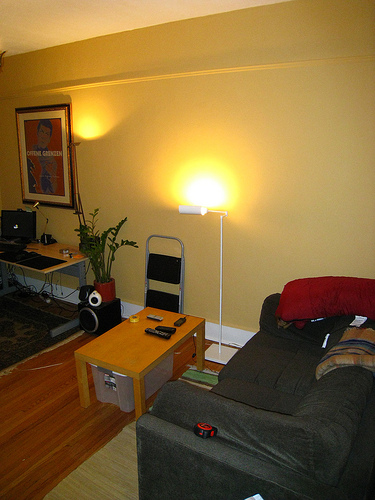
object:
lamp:
[177, 177, 239, 365]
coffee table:
[74, 307, 206, 421]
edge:
[146, 306, 204, 320]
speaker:
[88, 291, 102, 307]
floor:
[0, 309, 237, 500]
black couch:
[136, 292, 373, 498]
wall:
[0, 0, 374, 339]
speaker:
[78, 298, 122, 337]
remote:
[145, 327, 172, 340]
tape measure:
[193, 422, 217, 439]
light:
[167, 157, 237, 210]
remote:
[155, 325, 177, 334]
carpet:
[0, 295, 84, 378]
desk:
[0, 239, 84, 339]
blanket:
[275, 276, 375, 320]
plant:
[72, 208, 138, 285]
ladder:
[143, 233, 185, 314]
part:
[126, 354, 146, 368]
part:
[271, 389, 281, 393]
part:
[107, 314, 112, 324]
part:
[119, 459, 134, 473]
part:
[228, 303, 240, 315]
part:
[150, 327, 155, 331]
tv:
[0, 209, 36, 238]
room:
[4, 1, 372, 491]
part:
[260, 355, 289, 384]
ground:
[1, 290, 245, 497]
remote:
[147, 313, 164, 320]